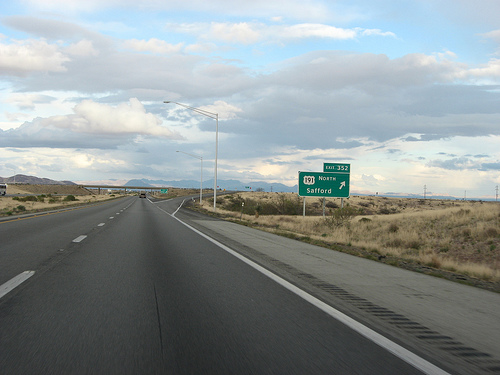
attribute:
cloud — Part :
[6, 94, 183, 151]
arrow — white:
[335, 178, 346, 192]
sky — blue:
[10, 9, 495, 149]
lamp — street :
[316, 176, 366, 201]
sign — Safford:
[274, 158, 349, 210]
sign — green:
[303, 163, 349, 197]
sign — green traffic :
[297, 162, 355, 216]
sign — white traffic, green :
[287, 167, 352, 211]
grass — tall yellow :
[185, 194, 499, 291]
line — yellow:
[1, 194, 128, 223]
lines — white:
[248, 262, 299, 302]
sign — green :
[300, 150, 350, 202]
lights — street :
[158, 96, 223, 208]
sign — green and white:
[297, 159, 356, 203]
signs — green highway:
[155, 163, 357, 199]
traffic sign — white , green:
[293, 152, 367, 207]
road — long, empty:
[2, 191, 498, 363]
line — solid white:
[168, 195, 454, 373]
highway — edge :
[1, 192, 498, 373]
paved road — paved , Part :
[6, 191, 492, 373]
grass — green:
[366, 200, 486, 262]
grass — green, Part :
[358, 220, 417, 259]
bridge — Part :
[84, 171, 204, 215]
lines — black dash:
[252, 237, 495, 369]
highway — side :
[71, 225, 324, 370]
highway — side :
[65, 215, 260, 351]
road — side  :
[156, 197, 185, 230]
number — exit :
[319, 162, 349, 182]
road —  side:
[164, 193, 188, 235]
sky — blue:
[188, 36, 327, 76]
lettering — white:
[303, 174, 339, 194]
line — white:
[114, 208, 122, 218]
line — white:
[105, 213, 115, 223]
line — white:
[95, 218, 105, 228]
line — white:
[71, 229, 90, 249]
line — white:
[0, 264, 39, 298]